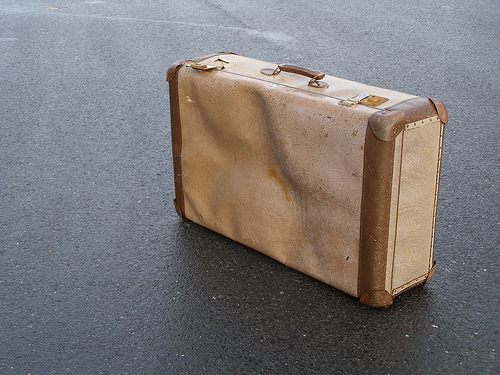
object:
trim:
[367, 99, 450, 307]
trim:
[166, 51, 236, 221]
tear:
[188, 60, 224, 75]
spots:
[350, 128, 360, 138]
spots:
[358, 145, 364, 153]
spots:
[321, 132, 331, 141]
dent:
[200, 86, 310, 237]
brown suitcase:
[162, 51, 450, 308]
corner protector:
[357, 288, 392, 306]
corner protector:
[369, 108, 405, 140]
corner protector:
[166, 60, 181, 81]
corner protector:
[425, 260, 435, 279]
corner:
[172, 197, 184, 218]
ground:
[0, 1, 500, 375]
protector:
[367, 107, 407, 142]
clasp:
[338, 89, 372, 110]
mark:
[180, 88, 198, 111]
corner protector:
[432, 98, 447, 122]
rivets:
[400, 120, 416, 128]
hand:
[259, 64, 326, 94]